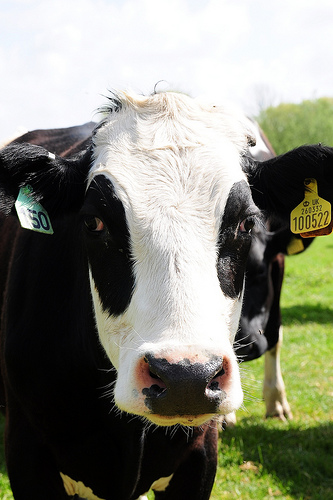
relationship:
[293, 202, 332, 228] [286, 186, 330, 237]
number on tag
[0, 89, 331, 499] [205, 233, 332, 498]
dairy cow in field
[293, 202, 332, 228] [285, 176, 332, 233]
number with tag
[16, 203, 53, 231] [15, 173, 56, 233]
number with tag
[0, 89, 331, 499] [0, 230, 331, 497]
dairy cow standing in grass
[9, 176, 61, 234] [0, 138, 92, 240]
tag in ear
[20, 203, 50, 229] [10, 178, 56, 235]
150 on tag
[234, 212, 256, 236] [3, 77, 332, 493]
eyeball of cow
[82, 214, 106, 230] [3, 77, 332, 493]
eyeball of cow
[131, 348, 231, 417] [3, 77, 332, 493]
nose of cow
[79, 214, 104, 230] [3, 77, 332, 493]
right eye of cow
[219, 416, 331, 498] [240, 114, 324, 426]
shadow of cow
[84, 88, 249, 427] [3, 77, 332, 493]
white hair of cow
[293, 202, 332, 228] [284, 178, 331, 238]
number on tag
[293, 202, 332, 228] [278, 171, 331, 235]
number on tag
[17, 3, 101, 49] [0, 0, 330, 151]
cloud in sky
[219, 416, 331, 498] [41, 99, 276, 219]
shadow of cow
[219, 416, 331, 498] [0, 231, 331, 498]
shadow on ground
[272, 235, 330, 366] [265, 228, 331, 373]
grass covering ground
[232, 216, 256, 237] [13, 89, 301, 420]
left eye of cow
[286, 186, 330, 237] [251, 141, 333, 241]
tag on cow's ear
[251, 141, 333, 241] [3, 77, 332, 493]
cow's ear on cow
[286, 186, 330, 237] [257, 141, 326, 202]
tag on cow's ear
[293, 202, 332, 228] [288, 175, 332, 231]
number on yellow tag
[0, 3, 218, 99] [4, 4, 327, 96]
cloud on sky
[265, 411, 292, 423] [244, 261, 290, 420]
hoof on cow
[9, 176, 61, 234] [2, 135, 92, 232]
tag on ear